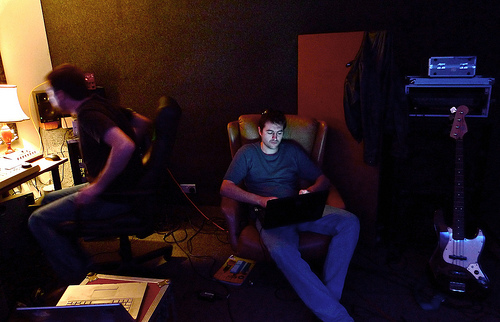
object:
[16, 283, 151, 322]
laptop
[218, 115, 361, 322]
man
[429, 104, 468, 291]
guitar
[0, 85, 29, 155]
lamp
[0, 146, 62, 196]
table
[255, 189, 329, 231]
lap